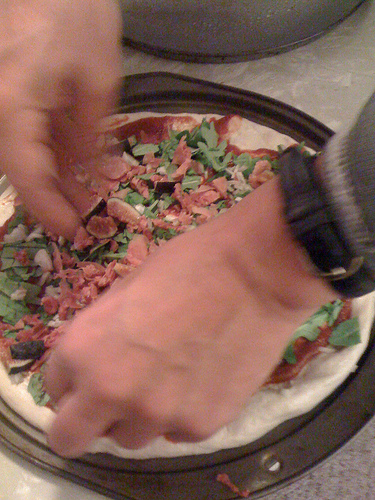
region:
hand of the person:
[65, 219, 308, 487]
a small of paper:
[208, 473, 249, 497]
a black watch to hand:
[250, 150, 368, 296]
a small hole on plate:
[259, 438, 291, 489]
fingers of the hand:
[61, 413, 139, 470]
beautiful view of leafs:
[26, 120, 286, 392]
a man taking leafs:
[29, 161, 364, 465]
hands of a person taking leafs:
[25, 31, 273, 459]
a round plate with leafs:
[17, 78, 365, 498]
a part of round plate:
[166, 15, 373, 98]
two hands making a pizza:
[3, 3, 370, 499]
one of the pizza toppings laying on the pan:
[215, 472, 248, 498]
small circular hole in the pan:
[264, 453, 280, 472]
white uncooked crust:
[245, 389, 337, 419]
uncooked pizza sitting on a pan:
[5, 77, 360, 491]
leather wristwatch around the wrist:
[276, 147, 373, 301]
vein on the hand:
[126, 334, 165, 357]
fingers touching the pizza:
[13, 108, 97, 253]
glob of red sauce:
[278, 366, 296, 381]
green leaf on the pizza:
[322, 315, 362, 353]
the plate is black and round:
[13, 102, 374, 475]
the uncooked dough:
[261, 389, 312, 419]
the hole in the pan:
[261, 454, 282, 472]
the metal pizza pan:
[270, 432, 352, 478]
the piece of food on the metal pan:
[214, 471, 244, 496]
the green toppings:
[2, 240, 32, 311]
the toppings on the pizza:
[125, 141, 198, 209]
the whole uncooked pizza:
[5, 95, 351, 454]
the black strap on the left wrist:
[275, 140, 369, 295]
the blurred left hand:
[49, 228, 286, 461]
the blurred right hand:
[3, 1, 126, 238]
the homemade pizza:
[4, 100, 373, 418]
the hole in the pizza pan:
[261, 456, 281, 473]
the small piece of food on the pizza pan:
[210, 470, 250, 498]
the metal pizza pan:
[99, 458, 356, 498]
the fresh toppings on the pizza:
[138, 144, 217, 212]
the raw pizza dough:
[261, 384, 308, 416]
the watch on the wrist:
[274, 141, 367, 297]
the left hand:
[42, 235, 281, 465]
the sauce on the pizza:
[295, 340, 318, 369]